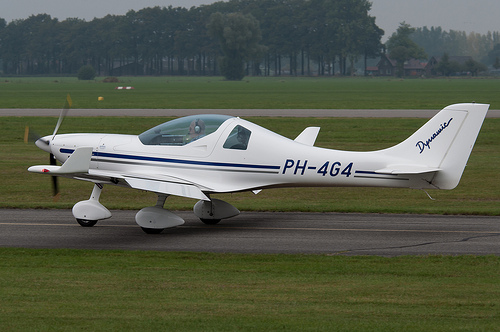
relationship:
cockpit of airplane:
[138, 112, 229, 146] [27, 102, 490, 234]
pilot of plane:
[187, 118, 205, 139] [33, 104, 484, 222]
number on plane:
[281, 155, 355, 182] [33, 104, 484, 222]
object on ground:
[96, 94, 105, 103] [1, 71, 499, 328]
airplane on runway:
[27, 102, 490, 234] [2, 205, 484, 257]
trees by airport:
[4, 0, 496, 74] [6, 78, 496, 328]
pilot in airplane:
[187, 118, 205, 139] [27, 102, 490, 234]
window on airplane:
[138, 114, 237, 146] [27, 102, 490, 234]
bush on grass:
[74, 64, 97, 81] [0, 73, 495, 328]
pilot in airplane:
[184, 117, 204, 146] [27, 102, 490, 234]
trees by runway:
[4, 0, 496, 74] [3, 208, 496, 252]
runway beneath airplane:
[0, 206, 499, 254] [27, 102, 490, 234]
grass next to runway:
[2, 243, 484, 330] [2, 205, 484, 257]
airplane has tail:
[27, 102, 490, 234] [377, 102, 484, 200]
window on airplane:
[214, 124, 254, 154] [27, 102, 490, 234]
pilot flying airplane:
[187, 118, 205, 139] [27, 102, 490, 234]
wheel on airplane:
[72, 206, 103, 230] [27, 102, 490, 234]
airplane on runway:
[27, 102, 490, 234] [1, 209, 484, 259]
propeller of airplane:
[23, 93, 72, 197] [27, 102, 490, 234]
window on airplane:
[138, 112, 233, 144] [27, 102, 490, 234]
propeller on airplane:
[23, 93, 72, 197] [23, 85, 480, 278]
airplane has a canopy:
[27, 102, 490, 234] [115, 99, 271, 164]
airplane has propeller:
[27, 102, 490, 234] [23, 93, 72, 197]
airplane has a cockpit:
[27, 102, 490, 234] [111, 92, 264, 174]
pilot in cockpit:
[187, 118, 205, 139] [86, 83, 274, 166]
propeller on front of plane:
[16, 66, 89, 246] [10, 47, 498, 258]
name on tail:
[399, 91, 465, 163] [322, 81, 486, 242]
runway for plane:
[14, 193, 497, 262] [22, 76, 498, 255]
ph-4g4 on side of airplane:
[263, 153, 377, 186] [27, 102, 490, 234]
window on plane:
[222, 124, 252, 151] [10, 47, 498, 258]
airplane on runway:
[27, 102, 490, 234] [6, 176, 497, 256]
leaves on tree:
[280, 15, 345, 40] [242, 0, 366, 95]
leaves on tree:
[116, 26, 236, 47] [119, 12, 209, 77]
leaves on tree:
[34, 18, 133, 79] [45, 21, 125, 62]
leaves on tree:
[116, 26, 236, 47] [132, 6, 259, 67]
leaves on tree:
[217, 0, 327, 88] [212, 19, 290, 86]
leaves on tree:
[389, 29, 424, 59] [374, 0, 417, 90]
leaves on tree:
[32, 22, 106, 82] [23, 11, 113, 91]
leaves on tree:
[74, 23, 154, 77] [86, 10, 159, 71]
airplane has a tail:
[27, 102, 490, 234] [382, 77, 498, 233]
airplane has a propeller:
[13, 68, 486, 253] [16, 81, 79, 214]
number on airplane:
[316, 161, 353, 178] [27, 102, 490, 234]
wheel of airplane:
[76, 218, 99, 227] [23, 99, 488, 234]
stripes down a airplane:
[61, 146, 429, 182] [27, 102, 490, 234]